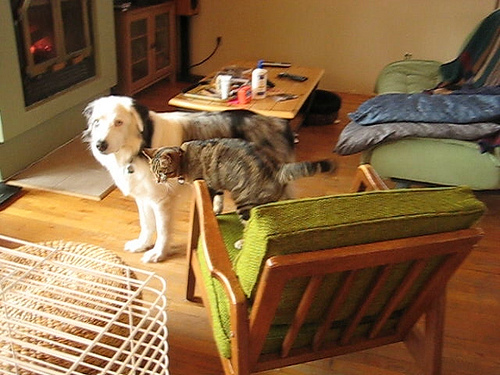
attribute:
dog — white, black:
[43, 90, 316, 263]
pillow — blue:
[290, 63, 481, 217]